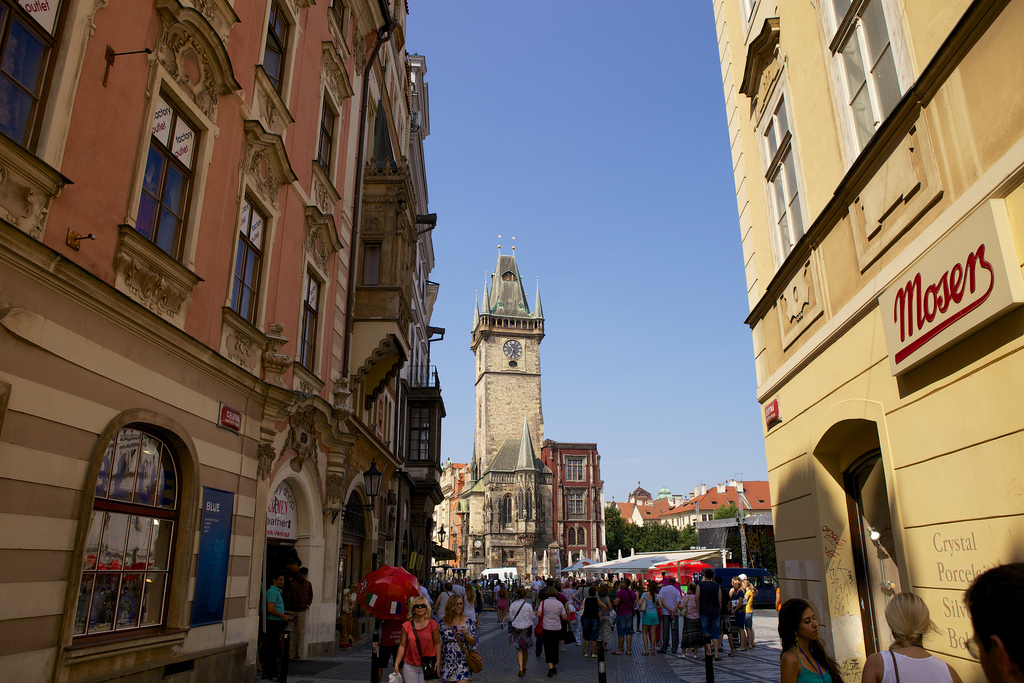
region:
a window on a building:
[81, 443, 183, 618]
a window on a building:
[344, 504, 371, 600]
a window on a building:
[560, 452, 584, 475]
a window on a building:
[239, 161, 277, 321]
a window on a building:
[301, 251, 334, 365]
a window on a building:
[318, 86, 347, 179]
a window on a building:
[265, 7, 288, 102]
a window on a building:
[131, 124, 195, 262]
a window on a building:
[232, 184, 277, 336]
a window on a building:
[66, 405, 188, 646]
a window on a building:
[751, 92, 800, 255]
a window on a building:
[262, 9, 304, 117]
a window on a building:
[315, 80, 345, 192]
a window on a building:
[564, 450, 587, 489]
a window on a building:
[553, 481, 591, 511]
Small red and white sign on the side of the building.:
[213, 394, 251, 437]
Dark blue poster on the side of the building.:
[187, 464, 245, 630]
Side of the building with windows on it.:
[725, 28, 830, 276]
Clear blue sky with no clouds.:
[465, 37, 517, 54]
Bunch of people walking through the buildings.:
[359, 543, 707, 680]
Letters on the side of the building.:
[918, 502, 999, 651]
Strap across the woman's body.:
[494, 593, 540, 628]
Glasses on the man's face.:
[956, 631, 1005, 680]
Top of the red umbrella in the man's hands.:
[351, 543, 421, 627]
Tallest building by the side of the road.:
[465, 183, 555, 572]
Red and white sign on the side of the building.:
[854, 233, 1014, 370]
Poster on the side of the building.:
[193, 437, 245, 638]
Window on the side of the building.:
[122, 22, 221, 297]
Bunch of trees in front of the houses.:
[608, 499, 684, 551]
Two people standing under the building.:
[260, 543, 292, 645]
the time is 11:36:
[499, 334, 526, 364]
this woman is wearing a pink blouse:
[389, 590, 451, 680]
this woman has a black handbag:
[386, 591, 447, 680]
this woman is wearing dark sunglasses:
[389, 590, 447, 680]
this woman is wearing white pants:
[385, 588, 453, 680]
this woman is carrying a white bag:
[382, 590, 447, 680]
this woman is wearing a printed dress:
[430, 584, 484, 680]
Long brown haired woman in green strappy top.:
[773, 597, 846, 680]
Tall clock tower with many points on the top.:
[467, 232, 547, 572]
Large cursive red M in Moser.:
[888, 274, 926, 341]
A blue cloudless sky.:
[401, 0, 769, 494]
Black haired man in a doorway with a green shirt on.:
[259, 570, 291, 619]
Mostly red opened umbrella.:
[354, 559, 422, 618]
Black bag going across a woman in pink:
[406, 615, 445, 680]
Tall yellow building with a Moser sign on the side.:
[708, 2, 1022, 679]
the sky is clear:
[600, 238, 680, 369]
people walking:
[582, 579, 701, 655]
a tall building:
[477, 250, 538, 453]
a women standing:
[774, 589, 828, 673]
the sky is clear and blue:
[562, 227, 667, 348]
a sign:
[878, 260, 1016, 337]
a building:
[679, 474, 769, 520]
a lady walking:
[394, 594, 443, 680]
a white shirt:
[882, 655, 931, 676]